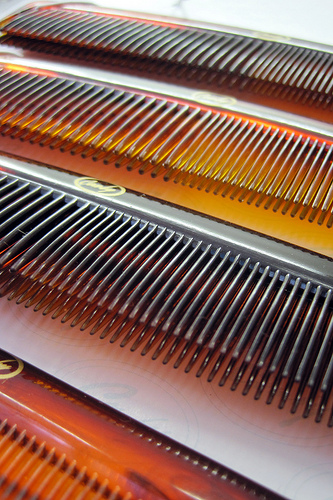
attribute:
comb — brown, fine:
[2, 163, 328, 425]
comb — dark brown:
[11, 4, 325, 102]